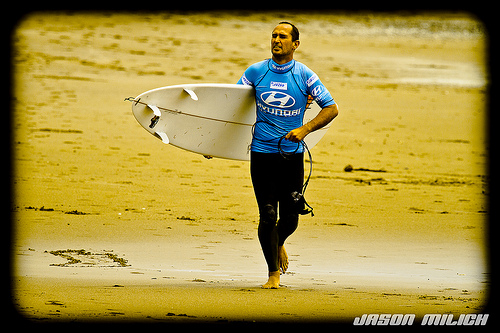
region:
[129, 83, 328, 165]
a long white surfboard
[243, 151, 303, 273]
a man's black swim pants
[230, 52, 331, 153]
a blue and white swim shirt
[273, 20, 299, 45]
a man's short cut black hair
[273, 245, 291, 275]
a man's barefoot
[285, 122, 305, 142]
the hand of a man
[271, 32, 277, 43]
the nose of a man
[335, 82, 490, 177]
a section of beach sand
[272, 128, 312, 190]
a long black cord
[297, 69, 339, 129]
the arm of a man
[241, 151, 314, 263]
guy with black wet suit pants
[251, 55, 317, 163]
guy with blue wet suit shirt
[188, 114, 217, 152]
guy carrying white surfboard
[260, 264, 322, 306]
guy wearing no shoes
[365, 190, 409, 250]
sand is orange colored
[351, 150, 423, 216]
tracks in orange sand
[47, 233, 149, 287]
marking in orange sand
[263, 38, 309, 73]
guy has his lips pulled back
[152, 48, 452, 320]
a man on the beach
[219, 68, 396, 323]
a man on the sand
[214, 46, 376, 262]
a surfer on the beach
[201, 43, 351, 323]
a surfer on the sand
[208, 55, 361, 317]
a man running on the sand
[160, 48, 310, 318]
a surfer running on the beach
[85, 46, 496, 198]
a man carrying a surfbaord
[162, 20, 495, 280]
a man holding a surfboard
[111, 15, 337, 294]
person carrying a white surfboard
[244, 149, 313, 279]
pair of black wet suit pants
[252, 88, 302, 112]
white logo on a blue shirt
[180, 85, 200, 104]
white fin on a large surf board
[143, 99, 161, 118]
white fin on a large surf board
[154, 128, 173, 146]
white fin on a large surf board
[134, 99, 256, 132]
black line down the middle of surfboard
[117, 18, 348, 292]
person wearing a blue shirt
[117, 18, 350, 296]
person with no shoes on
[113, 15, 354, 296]
person running down the beach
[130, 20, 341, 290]
Man running with a surfboard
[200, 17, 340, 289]
Man running along a beach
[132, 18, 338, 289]
Man carrying a surfboard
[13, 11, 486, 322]
Yellow beach sand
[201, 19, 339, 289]
Man wearing a blue water shirt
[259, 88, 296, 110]
White logo on a shirt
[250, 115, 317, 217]
Cable of a surfboard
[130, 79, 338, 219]
White surfboard with cable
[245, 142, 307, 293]
Black pants of a wetsuit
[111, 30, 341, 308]
a man hoilding a surfboard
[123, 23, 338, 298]
the man has black hair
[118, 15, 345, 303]
the man is wearing blue shirt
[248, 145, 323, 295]
the pants are black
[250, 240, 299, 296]
the feet are bare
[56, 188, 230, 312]
the sand is tan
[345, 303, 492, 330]
the words are white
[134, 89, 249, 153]
the bottom of surfboard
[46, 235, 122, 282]
tracks in the sand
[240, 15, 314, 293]
man carrying board on beaach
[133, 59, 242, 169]
white board carried by man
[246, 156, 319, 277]
wet suit worn by man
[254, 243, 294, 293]
man walking in tan sand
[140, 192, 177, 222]
tracks in tan colored sand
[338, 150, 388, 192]
tracks in tan colored sand